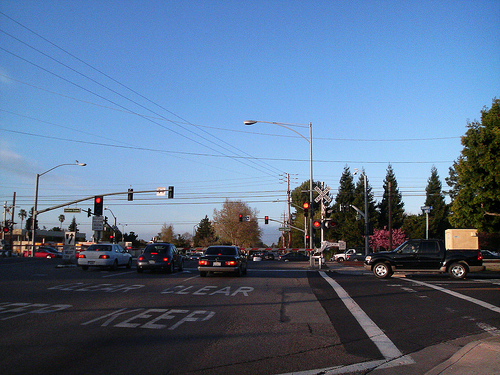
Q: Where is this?
A: This is at the street.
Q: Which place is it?
A: It is a street.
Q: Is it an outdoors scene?
A: Yes, it is outdoors.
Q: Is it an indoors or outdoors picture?
A: It is outdoors.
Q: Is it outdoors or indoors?
A: It is outdoors.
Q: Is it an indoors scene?
A: No, it is outdoors.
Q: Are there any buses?
A: No, there are no buses.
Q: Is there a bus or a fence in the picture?
A: No, there are no buses or fences.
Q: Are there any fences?
A: No, there are no fences.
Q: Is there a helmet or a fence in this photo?
A: No, there are no fences or helmets.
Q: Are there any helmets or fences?
A: No, there are no fences or helmets.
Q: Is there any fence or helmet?
A: No, there are no fences or helmets.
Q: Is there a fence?
A: No, there are no fences.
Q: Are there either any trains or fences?
A: No, there are no fences or trains.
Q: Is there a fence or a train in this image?
A: No, there are no fences or trains.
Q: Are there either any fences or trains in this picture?
A: No, there are no fences or trains.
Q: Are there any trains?
A: No, there are no trains.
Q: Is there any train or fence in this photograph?
A: No, there are no trains or fences.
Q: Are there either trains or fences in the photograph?
A: No, there are no trains or fences.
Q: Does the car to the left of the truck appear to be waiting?
A: Yes, the car is waiting.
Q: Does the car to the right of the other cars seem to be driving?
A: No, the car is waiting.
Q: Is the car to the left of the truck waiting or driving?
A: The car is waiting.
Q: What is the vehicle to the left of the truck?
A: The vehicle is a car.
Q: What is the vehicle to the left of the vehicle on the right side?
A: The vehicle is a car.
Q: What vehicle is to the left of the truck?
A: The vehicle is a car.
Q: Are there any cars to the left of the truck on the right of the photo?
A: Yes, there is a car to the left of the truck.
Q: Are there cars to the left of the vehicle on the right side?
A: Yes, there is a car to the left of the truck.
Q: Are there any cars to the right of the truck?
A: No, the car is to the left of the truck.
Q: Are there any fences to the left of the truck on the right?
A: No, there is a car to the left of the truck.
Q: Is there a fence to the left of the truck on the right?
A: No, there is a car to the left of the truck.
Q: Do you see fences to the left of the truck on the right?
A: No, there is a car to the left of the truck.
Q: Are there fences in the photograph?
A: No, there are no fences.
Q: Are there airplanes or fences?
A: No, there are no fences or airplanes.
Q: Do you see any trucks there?
A: Yes, there is a truck.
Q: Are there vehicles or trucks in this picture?
A: Yes, there is a truck.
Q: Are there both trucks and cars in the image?
A: Yes, there are both a truck and a car.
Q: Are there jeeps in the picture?
A: No, there are no jeeps.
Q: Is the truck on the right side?
A: Yes, the truck is on the right of the image.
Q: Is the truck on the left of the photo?
A: No, the truck is on the right of the image.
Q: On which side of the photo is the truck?
A: The truck is on the right of the image.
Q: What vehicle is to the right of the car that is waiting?
A: The vehicle is a truck.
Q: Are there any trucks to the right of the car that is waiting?
A: Yes, there is a truck to the right of the car.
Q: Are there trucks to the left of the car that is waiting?
A: No, the truck is to the right of the car.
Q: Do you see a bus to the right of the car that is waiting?
A: No, there is a truck to the right of the car.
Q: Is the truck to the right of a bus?
A: No, the truck is to the right of a car.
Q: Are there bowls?
A: No, there are no bowls.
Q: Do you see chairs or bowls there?
A: No, there are no bowls or chairs.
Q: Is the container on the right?
A: Yes, the container is on the right of the image.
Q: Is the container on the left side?
A: No, the container is on the right of the image.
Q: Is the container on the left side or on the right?
A: The container is on the right of the image.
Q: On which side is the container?
A: The container is on the right of the image.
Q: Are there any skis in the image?
A: No, there are no skis.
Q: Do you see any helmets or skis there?
A: No, there are no skis or helmets.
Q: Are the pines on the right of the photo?
A: Yes, the pines are on the right of the image.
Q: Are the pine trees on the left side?
A: No, the pine trees are on the right of the image.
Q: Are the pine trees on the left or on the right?
A: The pine trees are on the right of the image.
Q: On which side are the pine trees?
A: The pine trees are on the right of the image.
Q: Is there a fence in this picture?
A: No, there are no fences.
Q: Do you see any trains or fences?
A: No, there are no fences or trains.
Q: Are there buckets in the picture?
A: No, there are no buckets.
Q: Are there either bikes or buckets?
A: No, there are no buckets or bikes.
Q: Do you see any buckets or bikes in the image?
A: No, there are no buckets or bikes.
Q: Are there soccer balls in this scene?
A: No, there are no soccer balls.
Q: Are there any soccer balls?
A: No, there are no soccer balls.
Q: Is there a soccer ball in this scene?
A: No, there are no soccer balls.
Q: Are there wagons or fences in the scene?
A: No, there are no fences or wagons.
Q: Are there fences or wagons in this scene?
A: No, there are no fences or wagons.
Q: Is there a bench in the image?
A: No, there are no benches.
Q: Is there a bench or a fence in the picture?
A: No, there are no benches or fences.